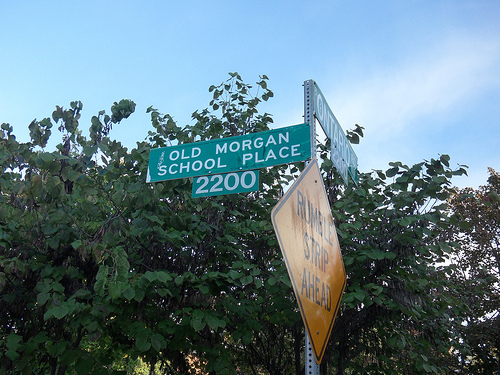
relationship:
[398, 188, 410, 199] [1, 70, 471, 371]
leaf on plant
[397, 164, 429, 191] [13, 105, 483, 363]
leaf on plant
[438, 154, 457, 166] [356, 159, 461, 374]
green leaf on plant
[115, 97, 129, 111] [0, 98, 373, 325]
leaf on plant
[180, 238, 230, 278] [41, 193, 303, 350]
leaf of plant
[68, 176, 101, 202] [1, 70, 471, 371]
leaf on plant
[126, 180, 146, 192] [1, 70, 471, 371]
leaf on plant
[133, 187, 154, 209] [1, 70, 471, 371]
leaf on plant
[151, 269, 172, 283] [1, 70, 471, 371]
leaf on plant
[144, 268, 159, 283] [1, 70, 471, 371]
leaf on plant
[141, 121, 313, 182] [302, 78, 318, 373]
sign on pole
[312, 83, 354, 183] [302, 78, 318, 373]
sign on pole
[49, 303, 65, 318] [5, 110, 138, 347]
leaf on a plant